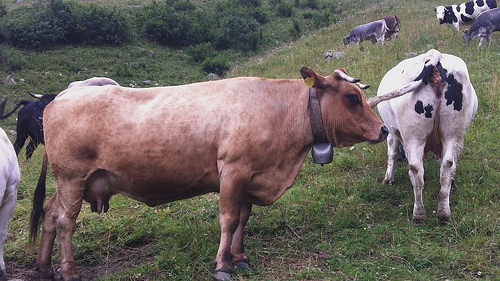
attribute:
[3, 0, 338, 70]
bushes — thick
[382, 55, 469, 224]
cow — black, white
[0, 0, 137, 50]
bush — green, leafy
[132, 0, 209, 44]
bush — leafy, green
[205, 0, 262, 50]
bush — leafy, green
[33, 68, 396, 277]
cow — brown, big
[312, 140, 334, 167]
cowbell — around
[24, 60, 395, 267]
cow — brown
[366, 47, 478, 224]
cow — white, black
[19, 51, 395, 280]
cow — tan colored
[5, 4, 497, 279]
grass — green, brown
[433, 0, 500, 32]
cow — looking towards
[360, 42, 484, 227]
cow — white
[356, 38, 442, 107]
tail — black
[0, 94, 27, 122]
tail — black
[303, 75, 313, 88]
tag — yellow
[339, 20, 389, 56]
cow — grey